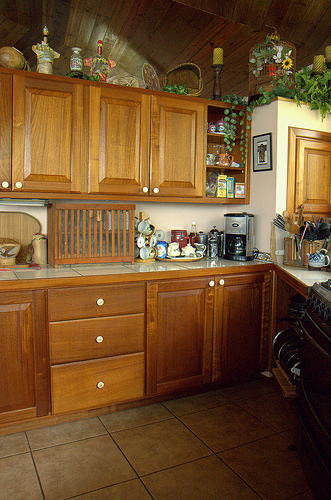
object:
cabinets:
[150, 91, 204, 197]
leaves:
[245, 115, 252, 121]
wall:
[248, 98, 277, 251]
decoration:
[252, 132, 272, 173]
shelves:
[205, 128, 246, 167]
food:
[217, 172, 227, 199]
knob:
[96, 297, 104, 305]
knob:
[95, 334, 103, 343]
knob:
[95, 380, 104, 388]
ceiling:
[0, 0, 330, 95]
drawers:
[47, 282, 145, 324]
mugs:
[137, 218, 153, 236]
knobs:
[306, 292, 313, 303]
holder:
[134, 210, 156, 265]